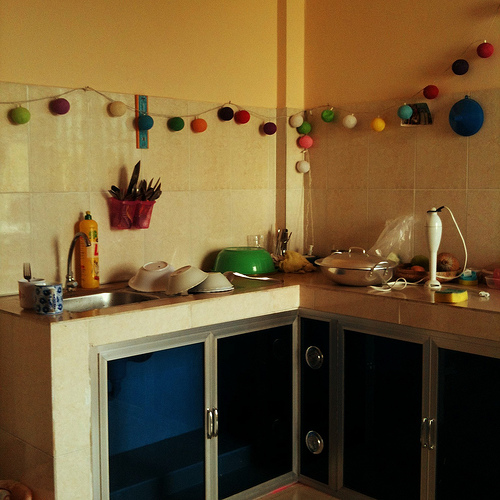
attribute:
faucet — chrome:
[57, 223, 95, 300]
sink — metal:
[60, 286, 167, 314]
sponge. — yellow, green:
[434, 282, 477, 317]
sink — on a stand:
[54, 277, 156, 317]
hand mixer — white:
[424, 207, 446, 292]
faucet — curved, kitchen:
[52, 209, 113, 305]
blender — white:
[416, 197, 456, 314]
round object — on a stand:
[298, 341, 327, 370]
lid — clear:
[313, 247, 395, 268]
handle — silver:
[346, 247, 366, 254]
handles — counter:
[201, 407, 221, 444]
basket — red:
[107, 201, 156, 230]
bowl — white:
[190, 270, 233, 292]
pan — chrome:
[306, 244, 407, 286]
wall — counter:
[171, 21, 282, 213]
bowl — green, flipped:
[196, 222, 316, 287]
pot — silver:
[314, 246, 397, 285]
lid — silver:
[315, 246, 398, 269]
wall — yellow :
[1, 2, 303, 107]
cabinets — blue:
[97, 338, 303, 498]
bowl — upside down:
[128, 259, 176, 291]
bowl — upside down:
[164, 265, 208, 295]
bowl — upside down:
[194, 272, 232, 289]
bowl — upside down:
[192, 287, 234, 291]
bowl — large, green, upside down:
[212, 245, 274, 276]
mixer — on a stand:
[424, 197, 486, 326]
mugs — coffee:
[18, 274, 63, 315]